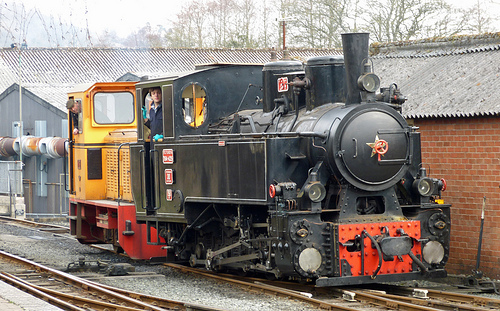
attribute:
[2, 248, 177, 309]
train track — trainless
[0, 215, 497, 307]
tracks — brown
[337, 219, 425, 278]
plate — metal, red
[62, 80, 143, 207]
cab — yellow